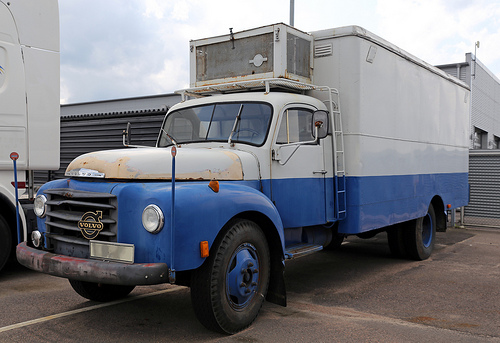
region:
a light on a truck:
[138, 204, 164, 236]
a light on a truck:
[208, 177, 220, 194]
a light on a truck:
[196, 238, 209, 256]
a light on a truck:
[447, 200, 454, 207]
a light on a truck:
[28, 229, 42, 242]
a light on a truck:
[32, 198, 46, 212]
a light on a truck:
[13, 178, 27, 187]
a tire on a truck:
[198, 215, 275, 331]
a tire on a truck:
[396, 208, 440, 256]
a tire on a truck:
[70, 275, 134, 302]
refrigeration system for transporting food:
[180, 26, 322, 96]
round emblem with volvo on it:
[75, 204, 109, 243]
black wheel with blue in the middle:
[199, 223, 276, 336]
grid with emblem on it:
[41, 192, 115, 251]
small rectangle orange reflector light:
[198, 236, 214, 261]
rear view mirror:
[308, 104, 333, 151]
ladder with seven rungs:
[317, 80, 358, 222]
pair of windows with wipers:
[152, 94, 279, 149]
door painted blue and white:
[267, 103, 339, 230]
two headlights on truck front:
[27, 183, 169, 243]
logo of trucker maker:
[75, 203, 112, 247]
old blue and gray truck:
[69, 37, 461, 299]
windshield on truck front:
[154, 96, 279, 153]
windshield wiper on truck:
[220, 98, 251, 150]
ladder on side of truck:
[314, 85, 353, 224]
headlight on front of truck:
[137, 196, 167, 244]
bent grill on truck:
[40, 183, 89, 210]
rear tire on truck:
[385, 199, 451, 267]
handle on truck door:
[306, 154, 336, 187]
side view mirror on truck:
[300, 100, 335, 156]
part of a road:
[409, 263, 451, 288]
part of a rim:
[232, 270, 259, 312]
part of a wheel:
[207, 240, 273, 323]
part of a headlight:
[128, 190, 185, 270]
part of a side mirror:
[306, 104, 331, 179]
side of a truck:
[371, 122, 458, 217]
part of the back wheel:
[408, 205, 445, 256]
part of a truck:
[348, 130, 405, 245]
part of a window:
[213, 97, 271, 132]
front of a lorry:
[18, 115, 169, 270]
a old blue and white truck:
[2, 23, 474, 311]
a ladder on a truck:
[314, 74, 360, 243]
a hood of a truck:
[60, 131, 250, 200]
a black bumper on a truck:
[0, 225, 180, 297]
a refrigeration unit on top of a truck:
[150, 27, 328, 113]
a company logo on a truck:
[73, 205, 113, 240]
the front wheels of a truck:
[149, 196, 286, 337]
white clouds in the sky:
[94, 4, 206, 91]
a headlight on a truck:
[115, 192, 164, 258]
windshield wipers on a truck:
[139, 88, 284, 154]